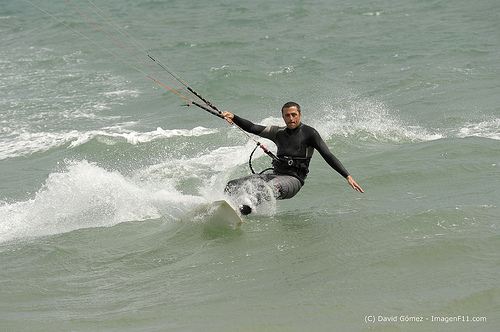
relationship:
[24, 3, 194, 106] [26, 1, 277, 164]
wire in set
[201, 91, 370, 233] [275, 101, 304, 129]
man has face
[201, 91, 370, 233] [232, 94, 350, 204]
man wearing wet suit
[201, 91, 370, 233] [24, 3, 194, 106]
man holding wire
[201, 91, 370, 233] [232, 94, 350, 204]
man in wet suit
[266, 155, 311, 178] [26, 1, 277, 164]
belt connected to wire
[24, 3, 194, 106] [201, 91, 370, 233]
wire connected to man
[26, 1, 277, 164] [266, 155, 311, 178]
set connected with belt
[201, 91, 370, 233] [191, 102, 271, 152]
man holding wire